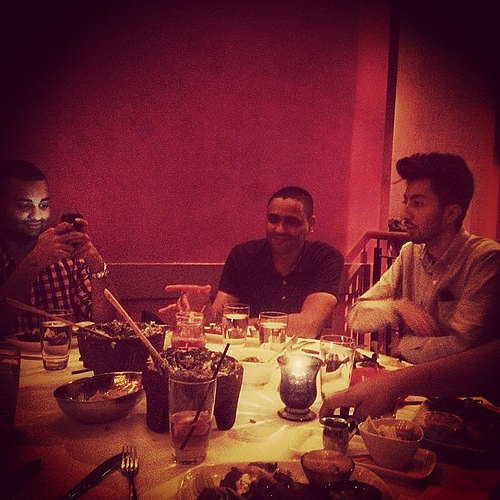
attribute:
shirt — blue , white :
[59, 209, 84, 237]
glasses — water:
[259, 310, 288, 352]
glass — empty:
[168, 375, 216, 462]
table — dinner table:
[24, 304, 456, 496]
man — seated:
[325, 153, 491, 383]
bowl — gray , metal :
[51, 371, 145, 424]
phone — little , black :
[55, 213, 93, 255]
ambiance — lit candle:
[269, 348, 322, 423]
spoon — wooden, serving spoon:
[101, 282, 191, 379]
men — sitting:
[339, 149, 498, 351]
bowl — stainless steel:
[32, 334, 187, 422]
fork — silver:
[119, 438, 142, 498]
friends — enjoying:
[0, 153, 498, 424]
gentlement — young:
[1, 155, 121, 340]